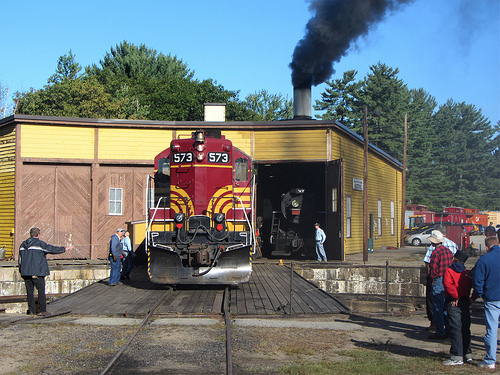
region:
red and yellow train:
[144, 129, 256, 286]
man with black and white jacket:
[15, 229, 75, 316]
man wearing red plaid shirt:
[425, 227, 456, 338]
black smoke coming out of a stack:
[289, 0, 415, 121]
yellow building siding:
[328, 128, 404, 255]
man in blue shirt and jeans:
[471, 235, 498, 370]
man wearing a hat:
[425, 229, 453, 339]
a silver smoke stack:
[291, 86, 313, 119]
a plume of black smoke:
[287, 0, 409, 88]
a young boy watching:
[441, 249, 472, 366]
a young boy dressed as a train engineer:
[441, 246, 475, 366]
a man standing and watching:
[424, 229, 451, 336]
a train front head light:
[175, 213, 183, 222]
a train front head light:
[215, 213, 224, 222]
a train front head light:
[196, 144, 203, 151]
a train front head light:
[196, 153, 203, 160]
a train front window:
[233, 157, 248, 181]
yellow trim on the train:
[149, 162, 263, 262]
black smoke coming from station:
[246, 3, 448, 157]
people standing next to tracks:
[380, 183, 492, 374]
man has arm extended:
[10, 203, 85, 307]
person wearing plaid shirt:
[418, 243, 452, 283]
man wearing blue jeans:
[477, 286, 499, 356]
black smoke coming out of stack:
[286, 0, 421, 120]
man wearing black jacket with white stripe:
[15, 226, 75, 316]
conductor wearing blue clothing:
[105, 225, 127, 285]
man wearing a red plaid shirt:
[425, 228, 455, 336]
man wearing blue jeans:
[470, 233, 498, 373]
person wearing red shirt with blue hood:
[440, 247, 476, 372]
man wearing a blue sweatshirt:
[472, 235, 499, 370]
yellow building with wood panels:
[1, 103, 410, 262]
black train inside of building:
[252, 155, 342, 262]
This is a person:
[7, 223, 76, 329]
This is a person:
[105, 227, 125, 287]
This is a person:
[103, 221, 125, 293]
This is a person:
[311, 220, 329, 265]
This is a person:
[446, 245, 477, 372]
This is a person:
[471, 230, 493, 371]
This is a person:
[426, 227, 449, 344]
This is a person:
[308, 216, 333, 267]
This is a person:
[12, 222, 73, 332]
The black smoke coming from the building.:
[279, 30, 364, 82]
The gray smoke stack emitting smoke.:
[285, 76, 317, 121]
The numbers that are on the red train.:
[166, 150, 233, 170]